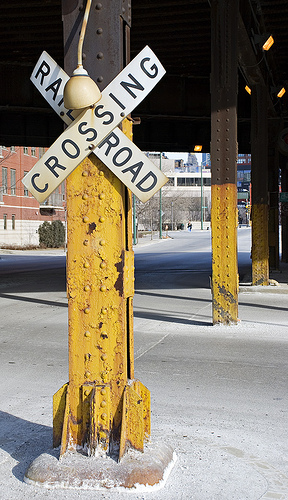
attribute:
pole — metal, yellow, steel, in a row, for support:
[47, 0, 153, 463]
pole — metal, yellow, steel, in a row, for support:
[207, 1, 242, 327]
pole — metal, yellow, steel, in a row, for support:
[249, 87, 276, 288]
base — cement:
[26, 439, 174, 490]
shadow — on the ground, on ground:
[2, 409, 60, 484]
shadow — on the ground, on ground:
[134, 308, 213, 335]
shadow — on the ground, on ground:
[1, 294, 67, 315]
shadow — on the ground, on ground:
[238, 301, 287, 317]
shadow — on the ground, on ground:
[135, 288, 214, 308]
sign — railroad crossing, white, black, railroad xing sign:
[21, 46, 170, 204]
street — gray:
[0, 228, 287, 500]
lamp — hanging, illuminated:
[259, 35, 277, 51]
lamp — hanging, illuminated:
[276, 85, 286, 102]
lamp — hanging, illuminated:
[242, 83, 251, 97]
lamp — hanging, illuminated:
[190, 144, 203, 154]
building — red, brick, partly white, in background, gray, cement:
[0, 148, 67, 258]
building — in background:
[134, 149, 218, 235]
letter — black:
[94, 105, 117, 128]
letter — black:
[121, 72, 143, 98]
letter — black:
[142, 56, 159, 80]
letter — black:
[30, 173, 50, 195]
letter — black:
[44, 156, 68, 177]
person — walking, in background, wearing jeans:
[188, 221, 194, 232]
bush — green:
[38, 222, 54, 251]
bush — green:
[51, 219, 67, 249]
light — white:
[62, 1, 100, 110]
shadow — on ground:
[1, 251, 253, 294]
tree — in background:
[135, 200, 155, 245]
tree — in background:
[164, 186, 189, 233]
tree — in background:
[181, 195, 200, 228]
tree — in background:
[237, 205, 247, 228]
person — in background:
[179, 223, 186, 231]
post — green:
[197, 165, 205, 232]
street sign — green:
[201, 205, 209, 213]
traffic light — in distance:
[246, 200, 254, 212]